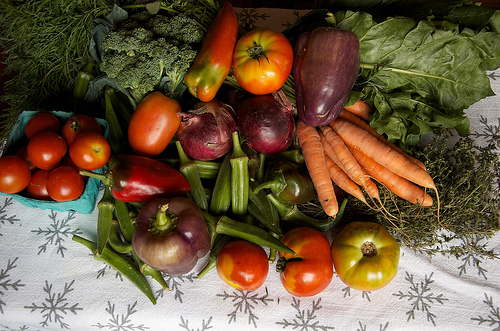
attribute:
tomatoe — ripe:
[48, 173, 81, 200]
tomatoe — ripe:
[68, 135, 111, 171]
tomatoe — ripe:
[64, 119, 100, 138]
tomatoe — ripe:
[30, 136, 67, 165]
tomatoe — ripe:
[23, 113, 63, 134]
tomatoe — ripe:
[30, 169, 50, 198]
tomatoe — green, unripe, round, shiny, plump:
[336, 222, 404, 290]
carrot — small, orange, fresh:
[323, 124, 367, 172]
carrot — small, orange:
[349, 126, 441, 178]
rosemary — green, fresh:
[432, 145, 494, 241]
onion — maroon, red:
[179, 100, 235, 161]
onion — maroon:
[231, 92, 296, 153]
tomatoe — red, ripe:
[277, 228, 331, 292]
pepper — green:
[262, 162, 323, 207]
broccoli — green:
[98, 16, 191, 95]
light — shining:
[365, 266, 385, 283]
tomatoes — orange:
[0, 112, 99, 191]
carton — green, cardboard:
[8, 109, 111, 210]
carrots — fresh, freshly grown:
[296, 116, 432, 212]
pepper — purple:
[295, 22, 360, 125]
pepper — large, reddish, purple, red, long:
[111, 150, 197, 204]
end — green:
[80, 167, 115, 187]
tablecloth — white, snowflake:
[5, 213, 489, 327]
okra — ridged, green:
[232, 143, 250, 215]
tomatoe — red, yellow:
[234, 29, 293, 92]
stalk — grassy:
[195, 10, 339, 120]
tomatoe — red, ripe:
[132, 91, 185, 157]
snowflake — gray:
[34, 278, 83, 327]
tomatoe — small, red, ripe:
[214, 237, 270, 292]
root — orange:
[431, 180, 447, 233]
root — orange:
[375, 195, 407, 216]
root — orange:
[421, 195, 429, 217]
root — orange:
[365, 198, 375, 212]